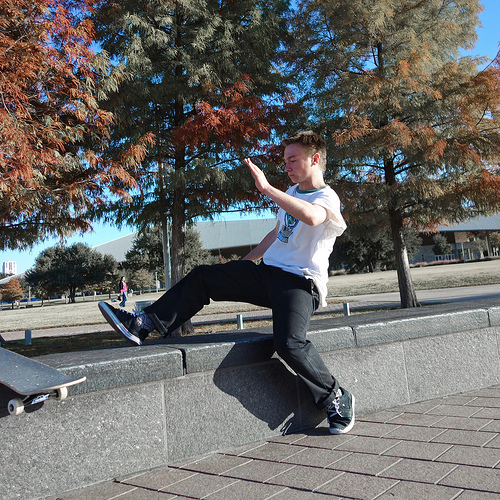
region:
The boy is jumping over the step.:
[161, 148, 364, 460]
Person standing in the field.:
[103, 252, 137, 312]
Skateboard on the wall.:
[6, 335, 64, 426]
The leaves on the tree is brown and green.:
[44, 66, 179, 193]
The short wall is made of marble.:
[58, 339, 308, 462]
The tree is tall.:
[345, 51, 460, 304]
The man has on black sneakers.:
[302, 376, 359, 432]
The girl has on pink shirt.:
[113, 278, 146, 300]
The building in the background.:
[65, 199, 263, 269]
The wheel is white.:
[7, 398, 50, 424]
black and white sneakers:
[96, 294, 158, 349]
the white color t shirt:
[268, 178, 346, 302]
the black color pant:
[142, 250, 358, 397]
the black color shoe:
[326, 384, 364, 439]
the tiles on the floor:
[407, 424, 458, 484]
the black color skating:
[9, 346, 84, 424]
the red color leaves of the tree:
[185, 75, 275, 145]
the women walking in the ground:
[103, 262, 138, 314]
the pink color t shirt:
[122, 281, 127, 293]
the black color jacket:
[117, 279, 124, 291]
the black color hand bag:
[111, 291, 124, 308]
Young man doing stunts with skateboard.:
[2, 128, 367, 433]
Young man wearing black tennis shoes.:
[93, 293, 153, 355]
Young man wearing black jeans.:
[141, 252, 351, 412]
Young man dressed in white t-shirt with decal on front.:
[258, 173, 348, 308]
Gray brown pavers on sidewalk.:
[360, 423, 498, 498]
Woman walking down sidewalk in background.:
[116, 273, 136, 311]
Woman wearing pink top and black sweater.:
[116, 278, 130, 295]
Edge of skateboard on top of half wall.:
[5, 347, 90, 427]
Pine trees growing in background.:
[323, 76, 499, 313]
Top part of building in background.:
[72, 207, 274, 263]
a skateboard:
[0, 351, 136, 437]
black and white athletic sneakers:
[86, 270, 411, 472]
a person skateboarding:
[0, 112, 402, 428]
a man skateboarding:
[242, 117, 370, 297]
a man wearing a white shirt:
[213, 95, 346, 298]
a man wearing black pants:
[166, 116, 380, 448]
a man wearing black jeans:
[160, 126, 387, 396]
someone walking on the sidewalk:
[76, 251, 183, 313]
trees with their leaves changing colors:
[1, 0, 156, 263]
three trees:
[0, 0, 481, 315]